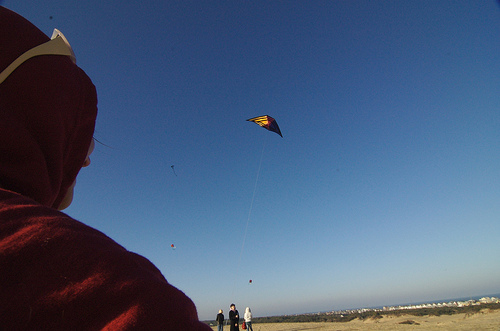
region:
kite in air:
[238, 101, 290, 149]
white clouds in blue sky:
[395, 33, 433, 114]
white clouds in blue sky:
[288, 85, 369, 179]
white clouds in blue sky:
[322, 143, 363, 181]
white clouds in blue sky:
[340, 173, 411, 233]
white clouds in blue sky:
[218, 199, 276, 239]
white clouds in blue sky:
[152, 152, 192, 210]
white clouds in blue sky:
[192, 72, 216, 103]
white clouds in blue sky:
[141, 66, 178, 100]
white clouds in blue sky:
[278, 0, 310, 41]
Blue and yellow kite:
[237, 104, 292, 143]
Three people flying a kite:
[208, 289, 263, 328]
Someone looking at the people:
[2, 2, 219, 329]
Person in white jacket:
[242, 305, 253, 326]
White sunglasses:
[0, 26, 81, 95]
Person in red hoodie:
[5, 2, 230, 329]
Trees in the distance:
[202, 287, 497, 329]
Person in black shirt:
[213, 304, 232, 329]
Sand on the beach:
[202, 310, 498, 330]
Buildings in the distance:
[316, 286, 498, 320]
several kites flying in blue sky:
[156, 103, 288, 285]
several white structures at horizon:
[278, 295, 499, 330]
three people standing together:
[211, 298, 260, 328]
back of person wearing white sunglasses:
[2, 8, 97, 212]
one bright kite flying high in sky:
[238, 107, 291, 287]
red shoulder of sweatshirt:
[5, 190, 200, 327]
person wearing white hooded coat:
[242, 305, 257, 329]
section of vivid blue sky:
[107, 18, 241, 125]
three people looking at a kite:
[208, 105, 287, 329]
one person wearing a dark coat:
[228, 302, 242, 329]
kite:
[241, 105, 281, 133]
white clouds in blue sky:
[385, 61, 406, 89]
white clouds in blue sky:
[394, 88, 448, 159]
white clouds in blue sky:
[327, 193, 385, 240]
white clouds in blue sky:
[167, 158, 231, 220]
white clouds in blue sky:
[365, 56, 413, 130]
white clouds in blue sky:
[152, 35, 199, 83]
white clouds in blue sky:
[292, 8, 347, 66]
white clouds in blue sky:
[110, 12, 168, 73]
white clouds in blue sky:
[187, 56, 237, 117]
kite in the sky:
[236, 107, 291, 139]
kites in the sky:
[168, 235, 256, 283]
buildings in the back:
[373, 295, 492, 306]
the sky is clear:
[312, 199, 391, 245]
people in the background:
[202, 300, 260, 329]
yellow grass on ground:
[341, 318, 450, 325]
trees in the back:
[262, 312, 344, 320]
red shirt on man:
[16, 233, 165, 317]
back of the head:
[0, 44, 78, 155]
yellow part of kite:
[252, 113, 269, 128]